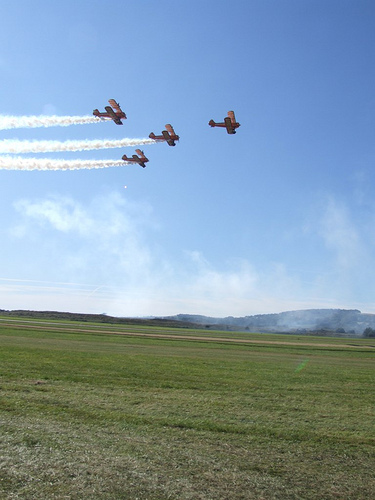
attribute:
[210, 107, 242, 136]
plane — flying, airborne, big, biplane, fixed wing, red, white, low altitude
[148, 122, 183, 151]
plane — flying, big, airborne, biplane, fixed wing, red, white, low altitude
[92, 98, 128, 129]
plane — flying, big, airborne, biplane, fixed wing, red, white, low altitude, two winged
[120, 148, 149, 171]
plane — flying, big, airborne, biplane, fixed wing, red, white, low altitude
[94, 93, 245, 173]
planes — flying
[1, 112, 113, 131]
smoke — linear, white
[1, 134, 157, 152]
smoke — linear, white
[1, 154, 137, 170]
smoke — linear, white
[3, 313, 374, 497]
field — open, grassy, green, wide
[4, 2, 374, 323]
sky — blue, cloudy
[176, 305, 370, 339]
hill — distant